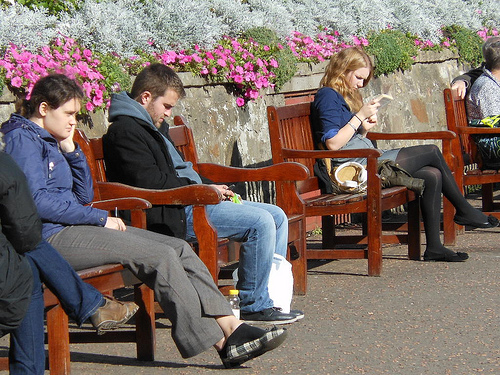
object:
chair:
[45, 127, 150, 374]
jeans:
[180, 198, 291, 311]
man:
[108, 55, 313, 302]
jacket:
[97, 90, 218, 237]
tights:
[396, 144, 489, 259]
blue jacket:
[2, 114, 128, 248]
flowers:
[1, 19, 498, 109]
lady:
[308, 47, 498, 265]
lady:
[3, 71, 288, 368]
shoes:
[219, 318, 286, 366]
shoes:
[236, 303, 303, 325]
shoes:
[420, 209, 497, 268]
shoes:
[89, 293, 139, 338]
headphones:
[332, 156, 369, 196]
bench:
[263, 90, 465, 275]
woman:
[3, 72, 288, 368]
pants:
[38, 217, 242, 364]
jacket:
[312, 86, 362, 154]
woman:
[312, 27, 494, 272]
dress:
[301, 86, 399, 179]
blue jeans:
[184, 195, 292, 313]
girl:
[307, 39, 498, 263]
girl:
[2, 71, 289, 365]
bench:
[438, 84, 498, 222]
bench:
[258, 99, 460, 277]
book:
[364, 88, 397, 132]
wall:
[0, 46, 483, 254]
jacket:
[0, 149, 41, 337]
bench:
[76, 113, 311, 298]